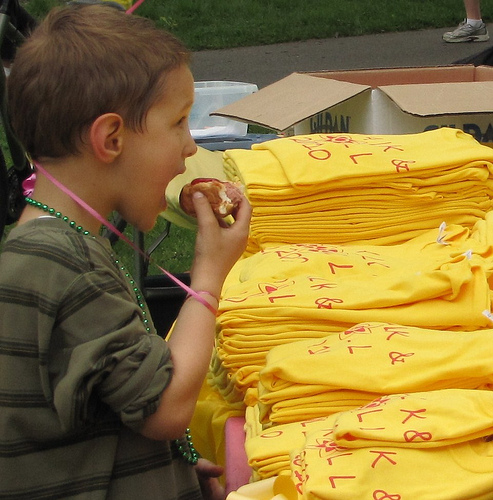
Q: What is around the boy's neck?
A: Ribbon.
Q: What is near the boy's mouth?
A: Partially eaten hot dog.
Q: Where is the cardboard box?
A: Behind shirts.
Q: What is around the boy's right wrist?
A: Pink ribbon.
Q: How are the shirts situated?
A: In stacks.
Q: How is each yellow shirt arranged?
A: Folded.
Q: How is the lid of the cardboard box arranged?
A: Open.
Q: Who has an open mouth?
A: Little boy.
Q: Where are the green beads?
A: Little boy's neck.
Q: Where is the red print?
A: Yellow shirts.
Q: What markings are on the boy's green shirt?
A: Black stripes.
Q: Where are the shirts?
A: Table.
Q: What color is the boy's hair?
A: Brown.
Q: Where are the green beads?
A: Boy's neck.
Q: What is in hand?
A: Food.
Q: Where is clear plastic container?
A: Left of box.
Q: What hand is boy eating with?
A: Right.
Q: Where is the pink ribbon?
A: Boy's neck.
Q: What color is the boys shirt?
A: Green/black.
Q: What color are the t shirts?
A: Yellow and red.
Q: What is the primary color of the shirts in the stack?
A: Yellow.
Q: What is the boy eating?
A: Hot dog.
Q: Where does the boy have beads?
A: Around his neck.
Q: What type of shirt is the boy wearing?
A: Sweatshirt.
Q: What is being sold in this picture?
A: Shirts.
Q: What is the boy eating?
A: Hotdog.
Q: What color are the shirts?
A: Yellow.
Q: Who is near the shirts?
A: Boy.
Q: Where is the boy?
A: Near shirts.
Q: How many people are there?
A: One.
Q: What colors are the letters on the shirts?
A: Red.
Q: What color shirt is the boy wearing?
A: Green.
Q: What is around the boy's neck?
A: Necklace.